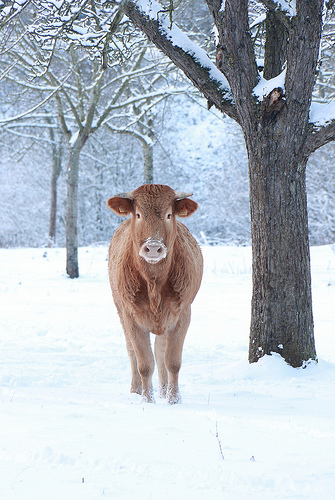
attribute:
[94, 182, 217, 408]
cow — brown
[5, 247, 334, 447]
snow — littered, white, covering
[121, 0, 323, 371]
tree — bare, snowy, brown, covered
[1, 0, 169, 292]
trees — bare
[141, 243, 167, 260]
nose — brown, covered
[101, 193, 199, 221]
ears — furry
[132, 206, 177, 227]
eyes — brown, black